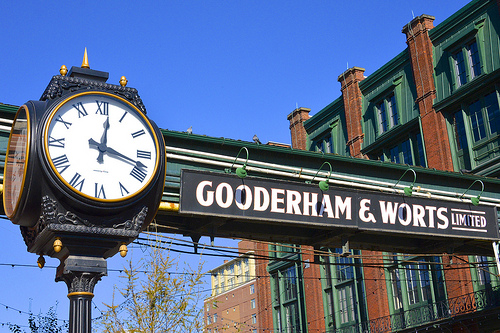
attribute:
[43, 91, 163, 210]
clock — black, large, reading, art deco, white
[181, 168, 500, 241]
sign — large, black, hanging, advertising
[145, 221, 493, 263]
cable — large, brown, long, dark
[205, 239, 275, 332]
building — brown, high, brick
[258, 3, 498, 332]
house — tall, green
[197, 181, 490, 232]
name — printed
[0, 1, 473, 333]
sky — blue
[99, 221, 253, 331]
plant — yellow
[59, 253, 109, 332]
post — gray, corinthian, black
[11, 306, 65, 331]
branch — sparse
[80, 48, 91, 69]
post — golden, gold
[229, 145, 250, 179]
light — small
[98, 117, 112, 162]
hand — hour